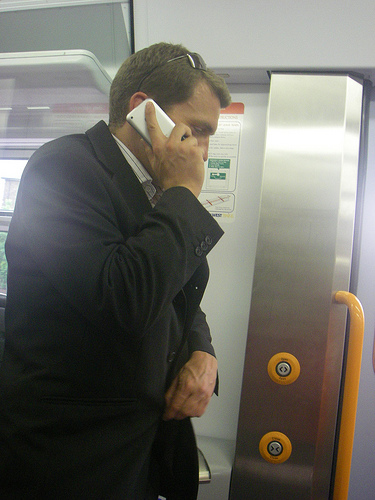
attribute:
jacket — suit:
[17, 133, 235, 456]